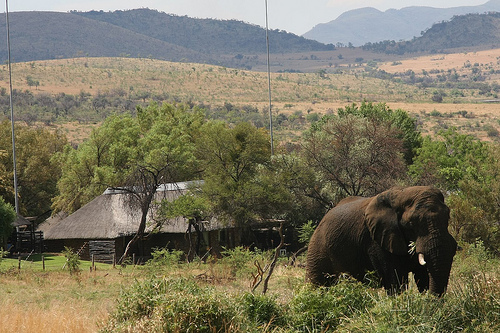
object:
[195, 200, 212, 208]
leaves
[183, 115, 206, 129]
leaves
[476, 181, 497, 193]
leaves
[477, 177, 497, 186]
leaves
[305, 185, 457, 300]
elephant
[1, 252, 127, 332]
grass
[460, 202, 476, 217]
leaves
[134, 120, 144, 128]
leaves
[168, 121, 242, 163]
green leaves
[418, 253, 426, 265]
tusk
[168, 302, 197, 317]
leaves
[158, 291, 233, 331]
bush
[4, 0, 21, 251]
pole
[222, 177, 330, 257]
trees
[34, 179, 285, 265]
hut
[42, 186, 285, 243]
roof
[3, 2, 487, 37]
sky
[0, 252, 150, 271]
fence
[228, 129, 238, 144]
leaf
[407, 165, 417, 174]
leaves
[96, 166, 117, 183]
leaves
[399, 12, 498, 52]
mountain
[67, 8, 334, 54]
mountain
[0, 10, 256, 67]
mountain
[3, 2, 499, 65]
range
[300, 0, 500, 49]
mountain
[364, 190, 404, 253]
ear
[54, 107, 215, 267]
tree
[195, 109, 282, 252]
tree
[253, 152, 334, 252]
tree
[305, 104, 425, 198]
tree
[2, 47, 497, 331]
ground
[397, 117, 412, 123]
leaves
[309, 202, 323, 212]
leaves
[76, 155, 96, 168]
leaves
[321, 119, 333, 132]
leaves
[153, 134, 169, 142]
leaves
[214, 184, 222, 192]
leaves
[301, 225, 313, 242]
leaves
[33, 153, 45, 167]
leaves